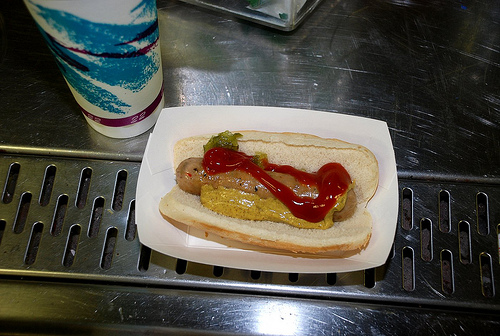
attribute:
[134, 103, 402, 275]
carton — small, paper, white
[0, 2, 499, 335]
counter — metal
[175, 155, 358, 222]
hotdog — brown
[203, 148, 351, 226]
ketchup — red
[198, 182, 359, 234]
mustard — yellow, spicy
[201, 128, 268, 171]
relish — green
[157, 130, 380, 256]
bun — white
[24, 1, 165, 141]
cup — white, blue, purple, paper, wine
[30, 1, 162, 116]
design — blue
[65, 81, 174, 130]
stripe — purple